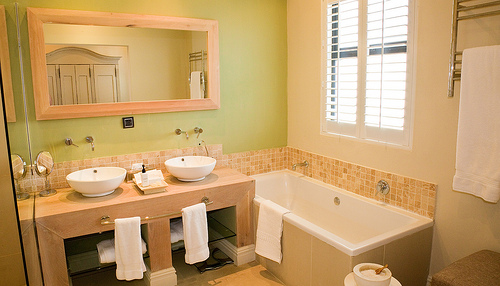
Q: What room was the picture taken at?
A: It was taken at the bathroom.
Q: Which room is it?
A: It is a bathroom.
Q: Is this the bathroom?
A: Yes, it is the bathroom.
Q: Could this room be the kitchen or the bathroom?
A: It is the bathroom.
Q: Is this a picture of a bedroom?
A: No, the picture is showing a bathroom.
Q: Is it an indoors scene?
A: Yes, it is indoors.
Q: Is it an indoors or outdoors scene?
A: It is indoors.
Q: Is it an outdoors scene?
A: No, it is indoors.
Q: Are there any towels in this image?
A: Yes, there is a towel.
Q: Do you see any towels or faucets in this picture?
A: Yes, there is a towel.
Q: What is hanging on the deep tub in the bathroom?
A: The towel is hanging on the bathtub.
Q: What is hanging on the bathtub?
A: The towel is hanging on the bathtub.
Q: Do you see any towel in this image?
A: Yes, there is a towel.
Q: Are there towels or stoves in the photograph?
A: Yes, there is a towel.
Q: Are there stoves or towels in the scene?
A: Yes, there is a towel.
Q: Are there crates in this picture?
A: No, there are no crates.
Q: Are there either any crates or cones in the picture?
A: No, there are no crates or cones.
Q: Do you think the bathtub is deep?
A: Yes, the bathtub is deep.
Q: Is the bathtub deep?
A: Yes, the bathtub is deep.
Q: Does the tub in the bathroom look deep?
A: Yes, the bathtub is deep.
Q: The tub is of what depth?
A: The tub is deep.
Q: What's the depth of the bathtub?
A: The tub is deep.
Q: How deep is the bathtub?
A: The bathtub is deep.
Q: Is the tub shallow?
A: No, the tub is deep.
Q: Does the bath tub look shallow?
A: No, the bath tub is deep.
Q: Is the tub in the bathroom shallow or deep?
A: The tub is deep.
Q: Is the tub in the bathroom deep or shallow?
A: The tub is deep.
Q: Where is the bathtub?
A: The bathtub is in the bathroom.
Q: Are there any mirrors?
A: Yes, there is a mirror.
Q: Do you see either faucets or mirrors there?
A: Yes, there is a mirror.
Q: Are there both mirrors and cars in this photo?
A: No, there is a mirror but no cars.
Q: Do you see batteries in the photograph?
A: No, there are no batteries.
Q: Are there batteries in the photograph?
A: No, there are no batteries.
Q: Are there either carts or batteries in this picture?
A: No, there are no batteries or carts.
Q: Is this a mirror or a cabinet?
A: This is a mirror.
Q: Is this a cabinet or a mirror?
A: This is a mirror.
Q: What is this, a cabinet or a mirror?
A: This is a mirror.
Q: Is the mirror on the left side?
A: Yes, the mirror is on the left of the image.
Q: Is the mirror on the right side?
A: No, the mirror is on the left of the image.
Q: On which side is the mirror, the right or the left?
A: The mirror is on the left of the image.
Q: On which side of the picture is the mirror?
A: The mirror is on the left of the image.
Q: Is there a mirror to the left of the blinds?
A: Yes, there is a mirror to the left of the blinds.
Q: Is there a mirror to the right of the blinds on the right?
A: No, the mirror is to the left of the blinds.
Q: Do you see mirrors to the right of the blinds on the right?
A: No, the mirror is to the left of the blinds.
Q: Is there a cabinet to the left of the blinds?
A: No, there is a mirror to the left of the blinds.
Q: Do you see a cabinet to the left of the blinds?
A: No, there is a mirror to the left of the blinds.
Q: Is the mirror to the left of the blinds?
A: Yes, the mirror is to the left of the blinds.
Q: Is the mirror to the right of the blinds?
A: No, the mirror is to the left of the blinds.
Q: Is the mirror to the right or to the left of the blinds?
A: The mirror is to the left of the blinds.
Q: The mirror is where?
A: The mirror is in the bathroom.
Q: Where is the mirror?
A: The mirror is in the bathroom.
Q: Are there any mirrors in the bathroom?
A: Yes, there is a mirror in the bathroom.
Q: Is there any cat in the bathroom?
A: No, there is a mirror in the bathroom.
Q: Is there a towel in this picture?
A: Yes, there is a towel.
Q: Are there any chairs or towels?
A: Yes, there is a towel.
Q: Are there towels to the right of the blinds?
A: Yes, there is a towel to the right of the blinds.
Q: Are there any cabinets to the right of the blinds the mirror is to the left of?
A: No, there is a towel to the right of the blinds.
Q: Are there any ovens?
A: No, there are no ovens.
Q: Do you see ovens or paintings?
A: No, there are no ovens or paintings.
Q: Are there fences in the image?
A: No, there are no fences.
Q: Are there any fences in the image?
A: No, there are no fences.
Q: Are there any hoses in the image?
A: No, there are no hoses.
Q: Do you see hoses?
A: No, there are no hoses.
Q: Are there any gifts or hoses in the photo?
A: No, there are no hoses or gifts.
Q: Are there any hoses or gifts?
A: No, there are no hoses or gifts.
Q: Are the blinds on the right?
A: Yes, the blinds are on the right of the image.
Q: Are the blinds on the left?
A: No, the blinds are on the right of the image.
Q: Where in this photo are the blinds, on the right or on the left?
A: The blinds are on the right of the image.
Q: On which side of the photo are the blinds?
A: The blinds are on the right of the image.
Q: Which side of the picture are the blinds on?
A: The blinds are on the right of the image.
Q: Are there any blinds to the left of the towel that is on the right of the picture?
A: Yes, there are blinds to the left of the towel.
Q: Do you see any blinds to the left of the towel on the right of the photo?
A: Yes, there are blinds to the left of the towel.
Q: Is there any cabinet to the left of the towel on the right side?
A: No, there are blinds to the left of the towel.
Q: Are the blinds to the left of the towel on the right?
A: Yes, the blinds are to the left of the towel.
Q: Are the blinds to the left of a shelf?
A: No, the blinds are to the left of the towel.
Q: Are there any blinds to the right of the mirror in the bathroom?
A: Yes, there are blinds to the right of the mirror.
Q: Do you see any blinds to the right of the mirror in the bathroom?
A: Yes, there are blinds to the right of the mirror.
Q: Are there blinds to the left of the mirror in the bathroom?
A: No, the blinds are to the right of the mirror.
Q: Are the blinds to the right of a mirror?
A: Yes, the blinds are to the right of a mirror.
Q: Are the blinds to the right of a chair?
A: No, the blinds are to the right of a mirror.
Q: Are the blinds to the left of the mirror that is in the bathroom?
A: No, the blinds are to the right of the mirror.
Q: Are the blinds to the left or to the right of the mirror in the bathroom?
A: The blinds are to the right of the mirror.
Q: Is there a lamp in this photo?
A: No, there are no lamps.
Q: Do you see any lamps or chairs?
A: No, there are no lamps or chairs.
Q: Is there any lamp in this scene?
A: No, there are no lamps.